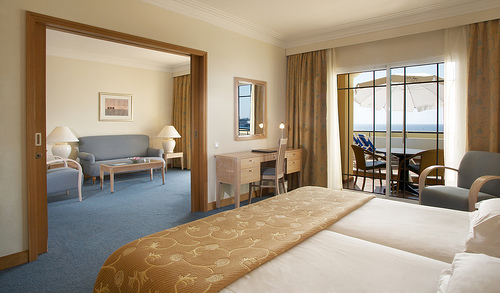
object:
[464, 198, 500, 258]
pillow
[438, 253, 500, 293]
pillow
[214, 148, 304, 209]
desk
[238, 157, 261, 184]
drawers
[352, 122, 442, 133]
ocean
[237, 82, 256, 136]
mirror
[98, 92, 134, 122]
painting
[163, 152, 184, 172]
table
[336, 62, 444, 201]
window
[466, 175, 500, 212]
arm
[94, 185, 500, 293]
bed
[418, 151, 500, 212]
chair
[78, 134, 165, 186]
couch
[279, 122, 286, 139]
desk lamp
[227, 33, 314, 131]
corner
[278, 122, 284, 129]
lightbulb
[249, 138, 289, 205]
chair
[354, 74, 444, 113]
patio umbrella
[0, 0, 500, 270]
wall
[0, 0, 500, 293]
hotel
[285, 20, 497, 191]
curtains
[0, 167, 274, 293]
blue carpet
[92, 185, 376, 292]
blanket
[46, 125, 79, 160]
lamp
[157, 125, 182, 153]
lamp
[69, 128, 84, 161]
shade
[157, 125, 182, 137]
shade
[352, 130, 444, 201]
patio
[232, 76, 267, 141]
frame